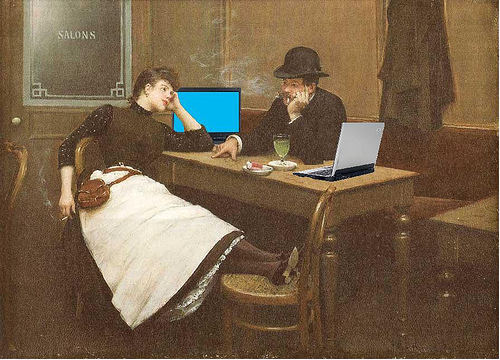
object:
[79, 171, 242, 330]
skirt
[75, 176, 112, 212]
bag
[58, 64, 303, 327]
woman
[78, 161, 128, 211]
purse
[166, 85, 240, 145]
laptops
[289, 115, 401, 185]
laptops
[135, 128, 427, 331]
table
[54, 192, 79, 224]
hand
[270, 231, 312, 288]
heels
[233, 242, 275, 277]
stockings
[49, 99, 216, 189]
black shirt